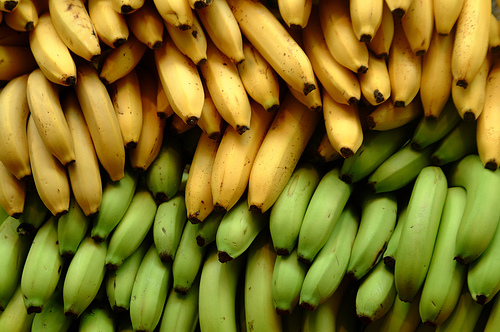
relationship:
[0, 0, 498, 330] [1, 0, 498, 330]
bunch of bananas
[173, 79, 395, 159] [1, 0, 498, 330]
brown ends of bananas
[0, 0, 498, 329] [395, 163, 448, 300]
bunch of banana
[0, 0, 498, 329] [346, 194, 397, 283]
bunch of banana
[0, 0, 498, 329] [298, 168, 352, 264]
bunch of banana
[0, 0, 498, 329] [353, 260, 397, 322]
bunch of banana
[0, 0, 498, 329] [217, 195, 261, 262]
bunch of banana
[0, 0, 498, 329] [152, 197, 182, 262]
bunch of banana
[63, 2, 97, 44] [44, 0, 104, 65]
brown spot on banana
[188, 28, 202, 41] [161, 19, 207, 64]
brown spot on banana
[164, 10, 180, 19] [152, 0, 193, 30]
brown spot on banana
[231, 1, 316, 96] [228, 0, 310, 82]
banana with brown spots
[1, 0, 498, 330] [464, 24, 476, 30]
bananas have brown spot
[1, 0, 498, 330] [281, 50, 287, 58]
bananas have brown spot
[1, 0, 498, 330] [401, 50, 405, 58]
bananas have brown spot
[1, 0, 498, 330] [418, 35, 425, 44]
bananas have brown spot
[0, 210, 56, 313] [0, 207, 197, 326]
banana in bunch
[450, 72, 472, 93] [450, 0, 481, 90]
brown end of banana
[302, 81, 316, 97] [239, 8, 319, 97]
brown end of banana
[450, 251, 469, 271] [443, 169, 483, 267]
brown end of banana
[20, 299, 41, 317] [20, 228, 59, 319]
brown end of banana